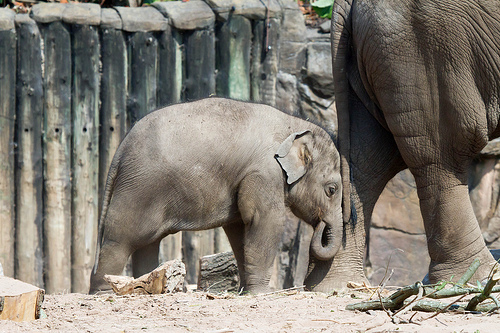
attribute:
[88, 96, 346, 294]
elephant — baby, leaning, behind, young, gray, nodging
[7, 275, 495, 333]
ground — sandy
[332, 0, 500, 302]
elephant — larger, gray, big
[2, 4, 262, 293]
fence — wooden, black, wood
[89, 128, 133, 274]
tail — hanging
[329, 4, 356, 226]
tail — hanging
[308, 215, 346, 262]
trunk — curled up, folded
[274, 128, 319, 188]
ear — flappy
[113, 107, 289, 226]
skin — gray, wrinkled, rough, smooth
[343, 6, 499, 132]
skin — gray, wrinkled, rough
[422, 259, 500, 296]
branch — broken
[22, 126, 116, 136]
holes — drilled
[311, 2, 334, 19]
leaf — green